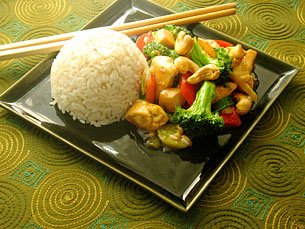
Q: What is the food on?
A: Plate.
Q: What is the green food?
A: Broccoli.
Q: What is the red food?
A: Red bell peppers.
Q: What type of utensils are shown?
A: Chopsticks.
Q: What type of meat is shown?
A: Chicken.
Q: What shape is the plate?
A: Square.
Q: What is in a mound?
A: Rice.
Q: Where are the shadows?
A: Bottom of the plate.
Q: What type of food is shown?
A: Asian.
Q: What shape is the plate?
A: Square.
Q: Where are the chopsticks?
A: On the plate.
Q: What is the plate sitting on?
A: A table.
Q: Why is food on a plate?
A: To be eaten.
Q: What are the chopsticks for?
A: To pick up the food.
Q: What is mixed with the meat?
A: Broccoli.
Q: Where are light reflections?
A: On the plate.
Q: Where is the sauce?
A: On plate.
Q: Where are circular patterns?
A: On the table.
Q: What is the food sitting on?
A: A plate.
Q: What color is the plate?
A: Black.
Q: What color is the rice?
A: White.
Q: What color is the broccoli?
A: Green.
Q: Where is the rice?
A: On the plate.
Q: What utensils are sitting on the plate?
A: Chopsticks.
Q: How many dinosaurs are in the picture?
A: Zero.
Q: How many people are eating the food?
A: Zero.